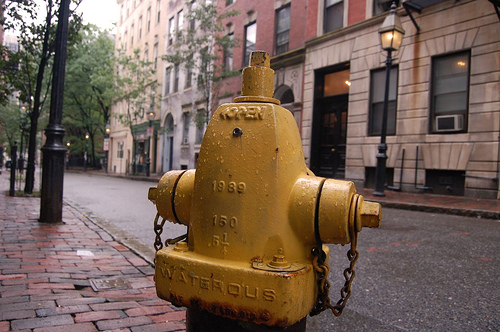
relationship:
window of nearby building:
[416, 49, 493, 134] [302, 10, 499, 225]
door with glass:
[307, 66, 364, 187] [320, 113, 344, 146]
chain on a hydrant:
[298, 221, 378, 328] [126, 27, 347, 291]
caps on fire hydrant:
[318, 178, 363, 248] [146, 48, 380, 332]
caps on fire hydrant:
[145, 168, 196, 227] [146, 48, 380, 332]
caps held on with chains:
[318, 178, 363, 248] [311, 246, 366, 316]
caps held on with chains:
[145, 168, 196, 227] [153, 212, 168, 247]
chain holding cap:
[314, 243, 359, 323] [323, 178, 382, 238]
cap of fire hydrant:
[323, 178, 382, 238] [135, 63, 350, 290]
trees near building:
[3, 1, 105, 138] [112, 2, 160, 99]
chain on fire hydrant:
[305, 241, 359, 318] [143, 46, 387, 330]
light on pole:
[379, 0, 406, 50] [373, 45, 392, 191]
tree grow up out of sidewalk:
[3, 1, 83, 194] [0, 169, 188, 330]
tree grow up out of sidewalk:
[1, 102, 26, 196] [0, 169, 188, 330]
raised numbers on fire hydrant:
[159, 104, 276, 304] [143, 46, 387, 330]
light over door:
[339, 79, 351, 89] [309, 59, 351, 173]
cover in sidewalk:
[86, 270, 133, 291] [0, 169, 188, 330]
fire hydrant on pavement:
[143, 46, 387, 330] [2, 170, 499, 329]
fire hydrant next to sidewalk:
[146, 48, 380, 332] [32, 230, 139, 324]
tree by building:
[78, 30, 115, 170] [107, 0, 167, 180]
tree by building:
[62, 53, 103, 166] [107, 0, 167, 180]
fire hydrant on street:
[146, 48, 380, 332] [310, 207, 497, 328]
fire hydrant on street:
[143, 46, 387, 330] [333, 207, 499, 329]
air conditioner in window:
[434, 115, 466, 136] [425, 47, 475, 134]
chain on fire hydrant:
[308, 235, 375, 315] [112, 44, 397, 330]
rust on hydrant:
[154, 291, 296, 330] [111, 54, 393, 330]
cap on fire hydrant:
[320, 178, 380, 252] [143, 46, 387, 330]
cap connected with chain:
[320, 178, 380, 252] [315, 247, 358, 312]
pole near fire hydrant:
[38, 12, 94, 258] [146, 48, 380, 332]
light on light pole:
[379, 4, 406, 54] [373, 50, 392, 199]